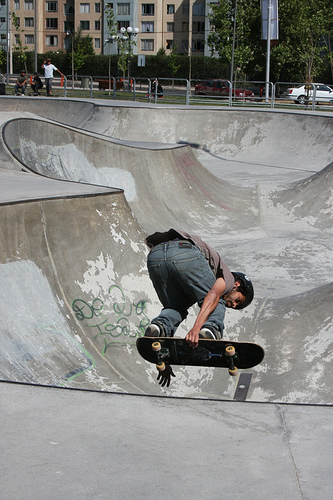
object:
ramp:
[0, 382, 332, 500]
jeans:
[145, 240, 229, 338]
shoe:
[143, 324, 162, 339]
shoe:
[196, 325, 218, 341]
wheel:
[151, 338, 161, 352]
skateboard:
[134, 336, 264, 378]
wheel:
[224, 345, 235, 358]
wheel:
[157, 361, 167, 372]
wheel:
[228, 363, 240, 377]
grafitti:
[70, 286, 151, 352]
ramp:
[0, 192, 135, 389]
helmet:
[233, 271, 255, 313]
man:
[41, 58, 65, 96]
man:
[31, 72, 43, 95]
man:
[13, 69, 31, 97]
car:
[197, 78, 256, 99]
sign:
[262, 1, 277, 40]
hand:
[183, 328, 200, 349]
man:
[143, 225, 255, 340]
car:
[287, 83, 332, 106]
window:
[142, 3, 156, 15]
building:
[0, 1, 203, 57]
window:
[141, 21, 155, 35]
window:
[139, 38, 155, 52]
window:
[118, 21, 130, 29]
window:
[120, 4, 132, 16]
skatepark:
[0, 88, 332, 499]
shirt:
[41, 65, 58, 80]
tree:
[270, 1, 331, 88]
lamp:
[120, 26, 128, 35]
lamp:
[126, 24, 134, 38]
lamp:
[133, 28, 140, 36]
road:
[4, 74, 192, 95]